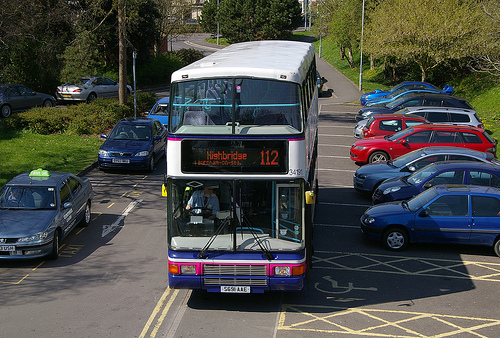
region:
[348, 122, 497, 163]
red car parked in the parking lot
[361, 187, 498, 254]
Left side of blue car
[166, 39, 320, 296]
Red, blue and white bus driving through the parking area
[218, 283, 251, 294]
Black and white license plate of the bus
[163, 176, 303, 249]
Front windshield of red, white and blue bus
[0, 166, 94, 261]
Blue tax parked on the side of the road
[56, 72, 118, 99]
Gray colored car in the distance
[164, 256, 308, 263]
White strip across the front of the bus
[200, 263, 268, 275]
Air vents at the front of the bus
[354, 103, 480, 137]
Silver colored parked car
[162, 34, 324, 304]
A double decker bus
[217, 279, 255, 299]
A white license plate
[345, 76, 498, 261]
A row of cars are parked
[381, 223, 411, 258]
A black round tire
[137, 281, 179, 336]
Two lines on the road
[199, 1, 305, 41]
Green leaves on a tree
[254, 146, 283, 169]
The number 112 on a bus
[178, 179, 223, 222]
Driver in the bus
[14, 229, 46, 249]
Headlight on a car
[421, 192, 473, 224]
Window on side of a car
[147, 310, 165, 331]
double line on the road.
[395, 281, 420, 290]
shadow in the parking space.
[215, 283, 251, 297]
license plate on bus.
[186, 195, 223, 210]
driver inside the bus.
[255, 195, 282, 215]
windshield of the bus.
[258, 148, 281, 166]
electronic number on bus.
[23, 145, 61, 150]
grass on the ground.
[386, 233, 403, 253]
hubcap of the vehicle.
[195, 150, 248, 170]
electronic words on bus.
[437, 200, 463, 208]
window of the car.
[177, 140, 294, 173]
Sign on front of a bus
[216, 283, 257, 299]
White and black license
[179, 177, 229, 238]
Bus driver in front seat of bus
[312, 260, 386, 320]
Handicap symbol painted on pavement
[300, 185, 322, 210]
left mirror on side of bus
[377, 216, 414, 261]
left front tire of blue car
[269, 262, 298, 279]
left headlight of bus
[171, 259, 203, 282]
right headlight of bus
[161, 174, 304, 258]
front windshield of bus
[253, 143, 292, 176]
The number of the bus is 112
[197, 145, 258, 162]
The orange writing says Highbridge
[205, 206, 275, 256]
Two black windshield wipers on the bus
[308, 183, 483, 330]
The shadow of the bus on the ground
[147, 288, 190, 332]
Double yellow lines painted on the ground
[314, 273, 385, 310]
A yellow handicapped sign painted on the ground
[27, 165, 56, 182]
A small green topper on the blue car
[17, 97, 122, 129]
Small green bushes in the short grass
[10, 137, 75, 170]
Short green grass grows on the field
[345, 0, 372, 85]
A tall, thin metal pole